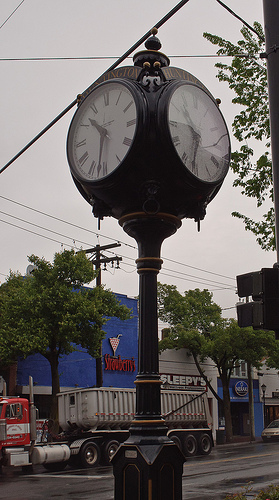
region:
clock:
[66, 74, 152, 192]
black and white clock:
[160, 81, 228, 196]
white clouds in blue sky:
[31, 31, 62, 64]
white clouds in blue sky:
[169, 245, 203, 260]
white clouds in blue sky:
[19, 22, 72, 78]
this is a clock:
[161, 73, 238, 186]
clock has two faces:
[75, 69, 241, 234]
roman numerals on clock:
[57, 85, 149, 183]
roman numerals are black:
[51, 78, 161, 191]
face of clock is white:
[70, 78, 153, 189]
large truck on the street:
[0, 363, 227, 477]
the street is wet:
[19, 424, 270, 496]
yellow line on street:
[186, 447, 267, 478]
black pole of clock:
[125, 230, 166, 416]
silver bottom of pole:
[128, 375, 167, 385]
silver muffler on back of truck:
[27, 376, 39, 439]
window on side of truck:
[7, 401, 26, 421]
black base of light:
[106, 437, 181, 497]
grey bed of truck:
[56, 391, 107, 420]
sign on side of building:
[148, 368, 216, 394]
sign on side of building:
[227, 377, 249, 396]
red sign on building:
[103, 349, 134, 368]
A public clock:
[66, 25, 231, 498]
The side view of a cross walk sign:
[235, 262, 278, 338]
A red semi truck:
[0, 373, 216, 476]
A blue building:
[3, 274, 137, 394]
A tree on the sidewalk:
[157, 280, 277, 441]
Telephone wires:
[0, 193, 247, 296]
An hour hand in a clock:
[88, 116, 107, 134]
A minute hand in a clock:
[96, 128, 107, 176]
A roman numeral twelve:
[101, 90, 110, 105]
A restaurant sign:
[102, 333, 136, 374]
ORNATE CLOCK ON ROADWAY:
[64, 29, 241, 239]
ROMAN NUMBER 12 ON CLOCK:
[99, 85, 112, 107]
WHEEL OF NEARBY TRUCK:
[77, 440, 103, 468]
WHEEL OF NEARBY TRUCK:
[194, 430, 213, 457]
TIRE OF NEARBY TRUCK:
[181, 431, 200, 458]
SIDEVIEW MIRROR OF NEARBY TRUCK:
[9, 398, 26, 424]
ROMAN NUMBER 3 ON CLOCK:
[122, 116, 141, 128]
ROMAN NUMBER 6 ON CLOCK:
[98, 159, 110, 176]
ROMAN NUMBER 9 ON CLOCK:
[68, 137, 93, 149]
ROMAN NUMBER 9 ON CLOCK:
[169, 114, 182, 131]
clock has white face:
[56, 77, 152, 178]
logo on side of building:
[101, 351, 140, 374]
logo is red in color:
[99, 356, 140, 374]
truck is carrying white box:
[47, 374, 213, 424]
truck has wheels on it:
[167, 428, 214, 463]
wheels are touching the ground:
[167, 427, 220, 463]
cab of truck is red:
[2, 389, 43, 455]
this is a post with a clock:
[59, 14, 249, 498]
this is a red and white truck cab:
[0, 370, 51, 481]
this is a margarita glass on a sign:
[100, 325, 132, 358]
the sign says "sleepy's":
[157, 366, 210, 396]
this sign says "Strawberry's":
[103, 346, 143, 381]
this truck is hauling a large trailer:
[3, 368, 222, 497]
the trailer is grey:
[50, 381, 222, 458]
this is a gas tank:
[30, 443, 73, 468]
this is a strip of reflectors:
[90, 404, 213, 429]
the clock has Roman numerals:
[63, 70, 159, 181]